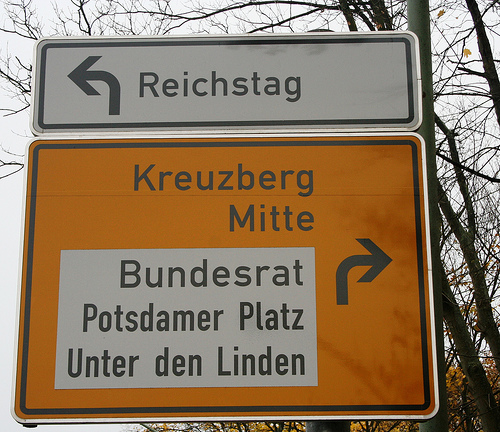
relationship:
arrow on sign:
[66, 55, 121, 117] [30, 30, 422, 136]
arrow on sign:
[337, 238, 393, 306] [10, 131, 441, 423]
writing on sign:
[135, 68, 304, 105] [30, 30, 422, 136]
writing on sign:
[131, 161, 316, 234] [10, 131, 441, 423]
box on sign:
[53, 246, 320, 392] [10, 131, 441, 423]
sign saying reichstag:
[30, 30, 422, 136] [135, 68, 304, 105]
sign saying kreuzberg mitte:
[10, 131, 441, 423] [131, 161, 316, 234]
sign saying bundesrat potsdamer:
[10, 131, 441, 423] [80, 255, 309, 340]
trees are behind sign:
[145, 367, 499, 432] [10, 131, 441, 423]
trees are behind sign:
[145, 367, 499, 432] [30, 30, 422, 136]